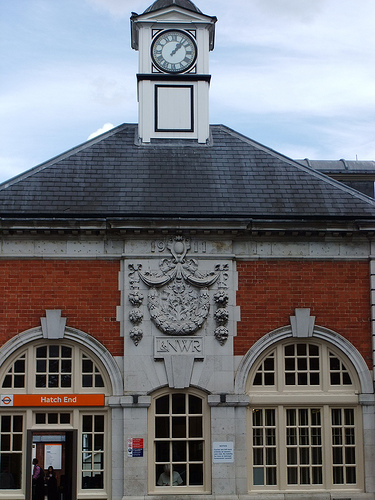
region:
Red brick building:
[0, 111, 374, 497]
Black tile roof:
[3, 93, 374, 241]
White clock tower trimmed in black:
[122, 0, 234, 150]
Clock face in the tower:
[142, 21, 205, 76]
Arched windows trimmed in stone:
[3, 303, 366, 498]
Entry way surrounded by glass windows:
[6, 379, 135, 499]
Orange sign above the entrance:
[4, 382, 114, 413]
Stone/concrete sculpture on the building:
[109, 231, 252, 375]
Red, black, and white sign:
[117, 426, 150, 467]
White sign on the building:
[193, 421, 243, 478]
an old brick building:
[21, 155, 352, 490]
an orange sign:
[7, 351, 162, 429]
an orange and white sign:
[6, 371, 209, 480]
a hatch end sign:
[16, 346, 193, 445]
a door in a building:
[13, 406, 136, 499]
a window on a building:
[120, 329, 296, 494]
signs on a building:
[112, 410, 320, 496]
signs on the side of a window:
[94, 375, 350, 498]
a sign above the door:
[1, 360, 95, 488]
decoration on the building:
[117, 229, 275, 357]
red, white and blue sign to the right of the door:
[124, 435, 141, 455]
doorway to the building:
[24, 424, 73, 494]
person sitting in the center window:
[156, 458, 179, 481]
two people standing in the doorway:
[30, 454, 54, 491]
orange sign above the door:
[2, 395, 100, 407]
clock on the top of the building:
[153, 29, 200, 72]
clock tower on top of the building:
[129, 3, 215, 141]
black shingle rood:
[1, 123, 373, 215]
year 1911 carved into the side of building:
[145, 235, 211, 255]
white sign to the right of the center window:
[211, 441, 235, 462]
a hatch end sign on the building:
[6, 386, 106, 427]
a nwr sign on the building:
[150, 334, 212, 394]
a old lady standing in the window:
[156, 453, 184, 494]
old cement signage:
[123, 229, 240, 390]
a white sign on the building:
[210, 435, 240, 467]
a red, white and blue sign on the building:
[124, 436, 150, 466]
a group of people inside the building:
[31, 436, 69, 489]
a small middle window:
[143, 385, 213, 490]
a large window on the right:
[243, 334, 330, 498]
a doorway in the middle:
[25, 420, 86, 494]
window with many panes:
[155, 399, 211, 493]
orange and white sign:
[30, 385, 91, 416]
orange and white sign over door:
[10, 394, 116, 412]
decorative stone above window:
[129, 260, 220, 337]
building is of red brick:
[273, 279, 303, 294]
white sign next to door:
[214, 433, 242, 475]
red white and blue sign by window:
[126, 430, 145, 462]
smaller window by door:
[80, 414, 112, 494]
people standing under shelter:
[28, 429, 62, 496]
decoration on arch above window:
[277, 308, 327, 338]